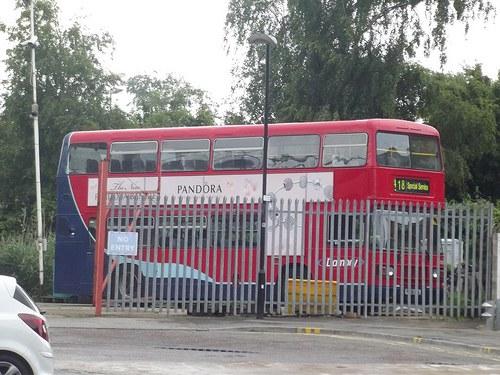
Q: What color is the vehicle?
A: Red.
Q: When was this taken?
A: During the day.